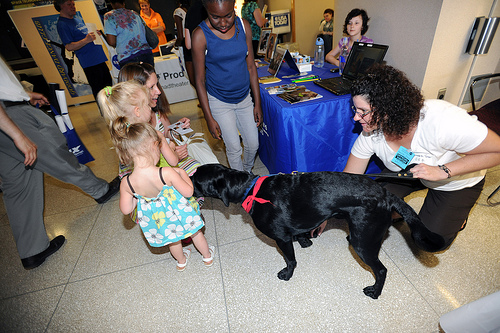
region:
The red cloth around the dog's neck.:
[234, 173, 271, 213]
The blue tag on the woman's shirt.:
[389, 146, 413, 171]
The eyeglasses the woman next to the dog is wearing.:
[348, 99, 382, 123]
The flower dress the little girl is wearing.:
[128, 180, 198, 238]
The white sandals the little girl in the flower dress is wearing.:
[161, 251, 222, 266]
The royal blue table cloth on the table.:
[240, 45, 369, 167]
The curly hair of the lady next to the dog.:
[343, 60, 422, 124]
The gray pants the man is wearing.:
[5, 98, 117, 240]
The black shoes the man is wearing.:
[8, 175, 122, 262]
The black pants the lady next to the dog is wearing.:
[389, 172, 474, 263]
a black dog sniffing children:
[104, 103, 455, 257]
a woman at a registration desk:
[257, 11, 377, 100]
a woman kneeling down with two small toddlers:
[91, 63, 208, 263]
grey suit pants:
[0, 96, 141, 266]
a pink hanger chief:
[232, 172, 279, 223]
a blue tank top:
[187, 20, 263, 115]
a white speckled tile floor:
[68, 263, 187, 328]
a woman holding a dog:
[230, 113, 486, 213]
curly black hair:
[345, 66, 427, 148]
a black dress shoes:
[13, 226, 79, 272]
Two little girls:
[99, 80, 216, 271]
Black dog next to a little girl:
[191, 162, 448, 300]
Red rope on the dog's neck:
[240, 175, 270, 213]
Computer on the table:
[313, 39, 388, 95]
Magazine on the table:
[277, 85, 324, 106]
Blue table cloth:
[256, 54, 377, 174]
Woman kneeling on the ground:
[342, 59, 497, 251]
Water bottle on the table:
[312, 35, 324, 68]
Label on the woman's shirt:
[390, 145, 414, 171]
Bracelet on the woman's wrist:
[437, 162, 452, 179]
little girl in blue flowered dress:
[78, 64, 225, 284]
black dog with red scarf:
[190, 161, 431, 271]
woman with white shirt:
[342, 60, 470, 200]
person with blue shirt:
[178, 18, 270, 125]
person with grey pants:
[2, 104, 107, 254]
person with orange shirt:
[135, 8, 182, 58]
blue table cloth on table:
[241, 34, 368, 179]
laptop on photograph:
[314, 25, 394, 109]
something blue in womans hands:
[362, 138, 430, 176]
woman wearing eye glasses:
[334, 94, 378, 139]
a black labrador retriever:
[191, 160, 424, 290]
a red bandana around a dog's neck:
[235, 180, 276, 214]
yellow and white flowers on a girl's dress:
[127, 192, 201, 248]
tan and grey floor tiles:
[62, 263, 170, 328]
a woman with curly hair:
[349, 80, 474, 262]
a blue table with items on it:
[269, 38, 360, 113]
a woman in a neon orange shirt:
[133, 2, 169, 60]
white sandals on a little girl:
[164, 247, 221, 267]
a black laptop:
[316, 45, 383, 102]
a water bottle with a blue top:
[303, 32, 328, 71]